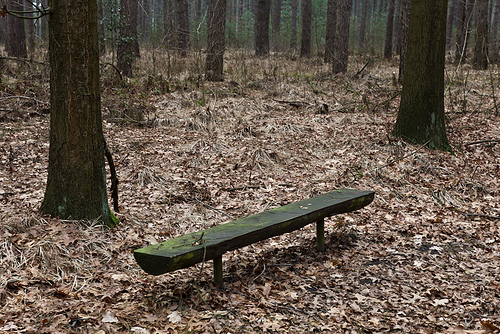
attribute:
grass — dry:
[207, 121, 302, 172]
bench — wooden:
[129, 182, 373, 279]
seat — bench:
[134, 180, 372, 274]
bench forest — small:
[125, 155, 450, 332]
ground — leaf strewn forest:
[1, 69, 471, 330]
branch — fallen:
[98, 134, 130, 216]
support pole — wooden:
[211, 254, 225, 289]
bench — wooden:
[134, 185, 376, 285]